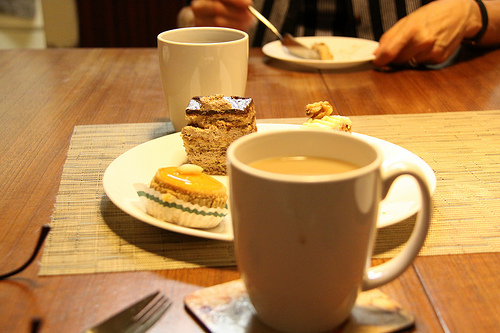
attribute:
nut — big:
[306, 89, 353, 119]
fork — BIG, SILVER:
[86, 287, 173, 332]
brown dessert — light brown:
[145, 165, 226, 209]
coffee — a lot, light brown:
[245, 154, 360, 177]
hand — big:
[373, 2, 472, 71]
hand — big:
[189, 0, 256, 32]